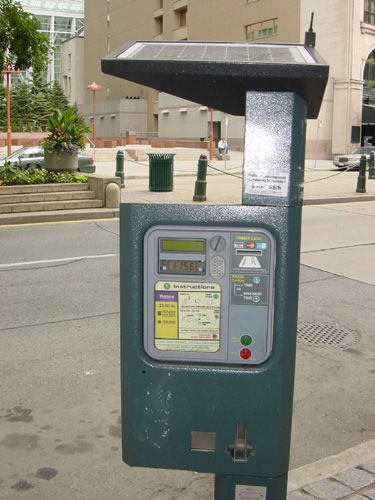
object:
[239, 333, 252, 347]
button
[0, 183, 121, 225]
stairs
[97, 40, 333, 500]
meter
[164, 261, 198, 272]
time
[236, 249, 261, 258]
card slot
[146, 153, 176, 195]
trash can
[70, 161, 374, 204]
sidewalk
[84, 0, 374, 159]
building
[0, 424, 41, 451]
water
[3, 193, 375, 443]
street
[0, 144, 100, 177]
car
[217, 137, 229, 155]
person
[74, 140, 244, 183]
public area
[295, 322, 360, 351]
sewer grate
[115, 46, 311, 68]
solar panel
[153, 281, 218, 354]
instructions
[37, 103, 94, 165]
plants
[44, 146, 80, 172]
planter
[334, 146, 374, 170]
car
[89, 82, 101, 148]
street light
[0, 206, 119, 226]
curb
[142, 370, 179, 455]
scrapes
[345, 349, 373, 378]
stains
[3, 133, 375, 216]
plaza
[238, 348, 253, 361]
buttons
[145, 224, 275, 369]
panel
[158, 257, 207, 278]
window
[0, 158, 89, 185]
plantings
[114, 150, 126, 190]
pillars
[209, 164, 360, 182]
chain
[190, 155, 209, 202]
pillars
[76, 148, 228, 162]
steps